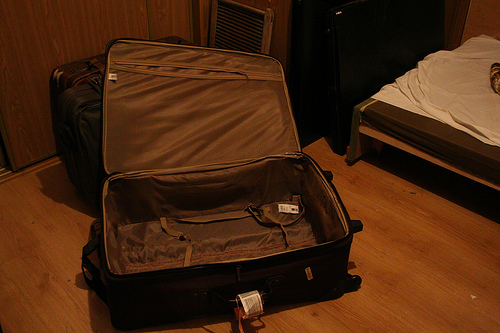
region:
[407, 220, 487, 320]
The floor is brown.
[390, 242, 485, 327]
The floor is made from wood.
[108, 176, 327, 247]
The inside of the suitcase is brown.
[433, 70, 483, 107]
The sheet on the bed is white.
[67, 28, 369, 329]
The suitcase is opened.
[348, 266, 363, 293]
The suitcase wheel is black.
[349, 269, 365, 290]
The suitcase wheel is round.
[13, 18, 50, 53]
The wall is brown.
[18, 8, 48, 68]
The wall is made of wood.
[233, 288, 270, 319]
The tag on the suitcase is white and black.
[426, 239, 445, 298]
There is a wood floor that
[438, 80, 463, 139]
there is a cot here that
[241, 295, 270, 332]
There is a tag on this luggage here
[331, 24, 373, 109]
There is a black piece of luggage here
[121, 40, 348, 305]
This photo has a very high quality to it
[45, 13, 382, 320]
the suitcase is open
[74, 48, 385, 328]
the suitcase is empty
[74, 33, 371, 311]
this is a black suitcase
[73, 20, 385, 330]
the suitcase has garment straps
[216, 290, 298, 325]
tags on a handle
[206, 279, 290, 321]
the barcode from an airport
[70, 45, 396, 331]
the suitcase has wheels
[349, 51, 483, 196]
a bed in a room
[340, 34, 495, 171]
the sheet is white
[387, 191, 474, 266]
the flooring is wood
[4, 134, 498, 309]
wooden panel flooring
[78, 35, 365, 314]
a black suitcase with a green inner lining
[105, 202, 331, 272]
several straps inside a suitcase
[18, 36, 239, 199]
A couple of small bags behind a suitcase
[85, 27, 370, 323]
The suitcase is open and empty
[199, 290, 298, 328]
There is a small white tag attached to the handle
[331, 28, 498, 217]
There is some white cloth on a small cot.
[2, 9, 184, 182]
A closet door behind several bags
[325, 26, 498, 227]
A small cot with some clothing on it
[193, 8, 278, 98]
A vent behind the open suitcase lid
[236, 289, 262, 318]
tag on the suitcase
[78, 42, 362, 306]
suitcase on the floor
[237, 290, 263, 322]
on the brown suitcase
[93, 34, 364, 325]
brown suitcase on the floor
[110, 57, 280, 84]
zipper on the suitcase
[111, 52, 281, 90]
zipper on the brown suitcase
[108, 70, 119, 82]
tag on the suitcase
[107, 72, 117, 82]
tag on the brown suitcase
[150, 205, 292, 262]
belts on the suitcase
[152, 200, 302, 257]
belts on the brown suitcase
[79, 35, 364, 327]
large open black suitcase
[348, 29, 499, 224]
small low thin bed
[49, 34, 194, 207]
large closed black bag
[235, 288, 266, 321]
small square thin white tag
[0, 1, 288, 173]
large flat brown wall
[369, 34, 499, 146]
small thin cloth white sheet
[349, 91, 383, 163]
square small wooden bed end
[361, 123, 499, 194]
long brown wooden bed plank